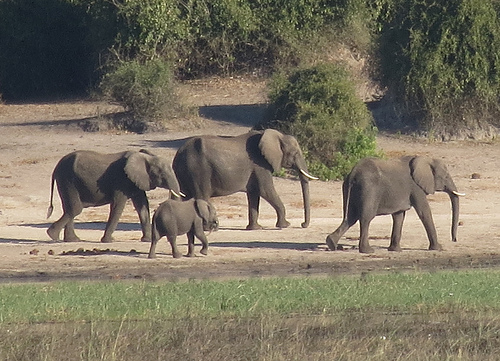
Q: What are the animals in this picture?
A: Elephants.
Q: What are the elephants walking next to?
A: Water.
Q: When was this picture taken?
A: During the day.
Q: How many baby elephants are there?
A: One.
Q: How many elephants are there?
A: Four.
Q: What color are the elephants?
A: Gray.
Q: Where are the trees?
A: On the other side of the elephants.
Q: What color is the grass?
A: Green.